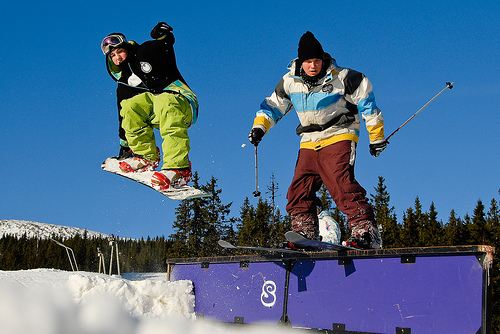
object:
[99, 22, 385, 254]
people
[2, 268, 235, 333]
snow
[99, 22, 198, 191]
person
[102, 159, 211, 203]
snowboard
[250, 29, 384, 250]
person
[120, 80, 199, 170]
pants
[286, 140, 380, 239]
pants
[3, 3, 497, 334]
air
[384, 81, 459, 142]
poles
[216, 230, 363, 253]
skiing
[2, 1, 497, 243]
sky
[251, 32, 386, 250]
skier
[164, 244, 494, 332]
platform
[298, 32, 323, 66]
cap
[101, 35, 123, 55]
goggles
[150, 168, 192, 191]
boots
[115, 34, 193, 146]
coat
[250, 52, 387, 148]
jacket